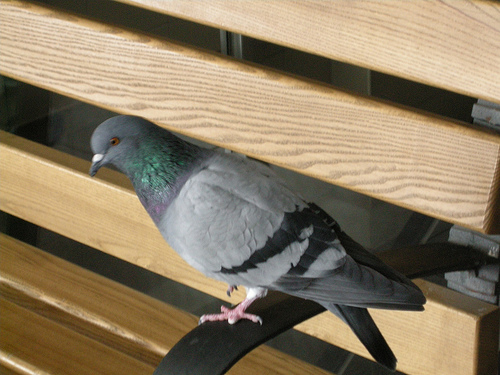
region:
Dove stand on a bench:
[71, 101, 436, 372]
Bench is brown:
[3, 4, 498, 372]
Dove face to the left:
[70, 103, 431, 373]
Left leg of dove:
[186, 293, 273, 331]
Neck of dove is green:
[133, 136, 190, 193]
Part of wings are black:
[213, 196, 344, 292]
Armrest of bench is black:
[139, 242, 453, 370]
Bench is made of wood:
[1, 3, 498, 368]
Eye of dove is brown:
[99, 128, 126, 155]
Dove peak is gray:
[80, 156, 107, 182]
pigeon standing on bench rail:
[82, 112, 432, 359]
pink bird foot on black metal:
[197, 297, 259, 335]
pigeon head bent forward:
[85, 108, 179, 198]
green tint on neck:
[130, 135, 191, 199]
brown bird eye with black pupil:
[105, 132, 123, 154]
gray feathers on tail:
[360, 267, 437, 327]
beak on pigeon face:
[77, 150, 104, 192]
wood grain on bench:
[308, 115, 390, 157]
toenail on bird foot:
[247, 313, 269, 332]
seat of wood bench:
[18, 332, 79, 360]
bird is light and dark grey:
[54, 86, 463, 363]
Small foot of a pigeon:
[187, 279, 273, 335]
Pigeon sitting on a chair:
[50, 86, 457, 361]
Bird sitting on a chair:
[54, 85, 430, 364]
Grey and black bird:
[52, 88, 469, 352]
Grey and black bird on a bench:
[60, 109, 427, 369]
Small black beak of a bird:
[75, 153, 120, 183]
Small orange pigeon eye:
[100, 127, 127, 149]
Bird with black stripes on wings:
[53, 91, 443, 373]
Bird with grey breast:
[67, 88, 441, 351]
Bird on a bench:
[59, 98, 454, 357]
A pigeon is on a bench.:
[70, 100, 462, 348]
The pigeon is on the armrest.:
[73, 113, 444, 373]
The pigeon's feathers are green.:
[122, 123, 219, 200]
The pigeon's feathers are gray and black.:
[190, 147, 444, 327]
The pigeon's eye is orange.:
[103, 130, 126, 150]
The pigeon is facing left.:
[67, 104, 454, 354]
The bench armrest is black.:
[134, 232, 489, 373]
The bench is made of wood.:
[1, 0, 498, 142]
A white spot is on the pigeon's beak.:
[84, 148, 109, 168]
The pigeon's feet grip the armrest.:
[187, 273, 277, 328]